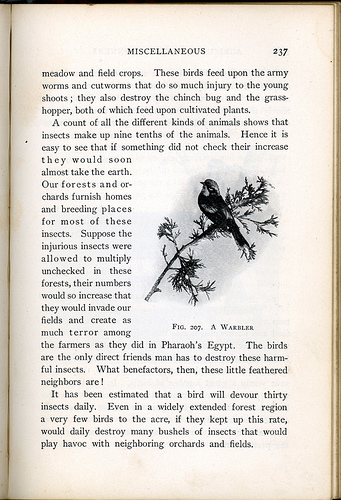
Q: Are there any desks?
A: No, there are no desks.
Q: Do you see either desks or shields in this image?
A: No, there are no desks or shields.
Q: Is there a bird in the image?
A: Yes, there is a bird.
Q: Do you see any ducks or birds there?
A: Yes, there is a bird.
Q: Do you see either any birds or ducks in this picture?
A: Yes, there is a bird.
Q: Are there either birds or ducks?
A: Yes, there is a bird.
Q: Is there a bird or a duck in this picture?
A: Yes, there is a bird.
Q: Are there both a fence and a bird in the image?
A: No, there is a bird but no fences.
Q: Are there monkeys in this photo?
A: No, there are no monkeys.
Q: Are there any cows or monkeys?
A: No, there are no monkeys or cows.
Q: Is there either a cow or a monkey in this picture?
A: No, there are no monkeys or cows.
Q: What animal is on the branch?
A: The bird is on the branch.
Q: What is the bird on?
A: The bird is on the branch.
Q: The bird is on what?
A: The bird is on the branch.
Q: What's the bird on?
A: The bird is on the branch.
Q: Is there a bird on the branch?
A: Yes, there is a bird on the branch.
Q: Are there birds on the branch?
A: Yes, there is a bird on the branch.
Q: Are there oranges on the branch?
A: No, there is a bird on the branch.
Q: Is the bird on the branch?
A: Yes, the bird is on the branch.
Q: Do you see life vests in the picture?
A: No, there are no life vests.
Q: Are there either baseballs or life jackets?
A: No, there are no life jackets or baseballs.